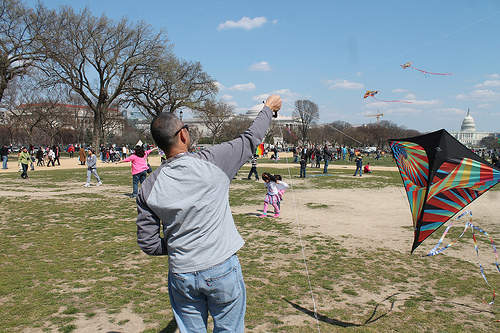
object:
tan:
[309, 209, 381, 231]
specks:
[185, 130, 187, 131]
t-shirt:
[123, 150, 151, 176]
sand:
[227, 184, 500, 275]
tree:
[478, 136, 499, 149]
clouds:
[195, 15, 500, 123]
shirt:
[135, 105, 274, 274]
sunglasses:
[175, 124, 189, 136]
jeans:
[168, 253, 247, 333]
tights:
[263, 202, 279, 212]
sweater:
[123, 149, 152, 175]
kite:
[388, 127, 500, 305]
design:
[387, 128, 500, 306]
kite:
[400, 61, 454, 79]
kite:
[363, 90, 415, 106]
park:
[0, 0, 500, 333]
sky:
[0, 0, 500, 139]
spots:
[0, 170, 500, 333]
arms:
[123, 149, 154, 162]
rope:
[276, 114, 321, 333]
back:
[134, 151, 247, 333]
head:
[150, 112, 191, 151]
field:
[0, 152, 500, 333]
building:
[447, 108, 496, 146]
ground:
[0, 150, 500, 333]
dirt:
[279, 174, 421, 246]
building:
[193, 103, 312, 149]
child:
[259, 172, 290, 218]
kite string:
[272, 98, 409, 333]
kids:
[258, 172, 290, 218]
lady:
[115, 145, 158, 199]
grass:
[0, 166, 500, 333]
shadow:
[281, 292, 495, 328]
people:
[79, 146, 86, 165]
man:
[135, 94, 282, 333]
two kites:
[363, 61, 454, 104]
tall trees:
[0, 0, 237, 160]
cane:
[365, 108, 384, 125]